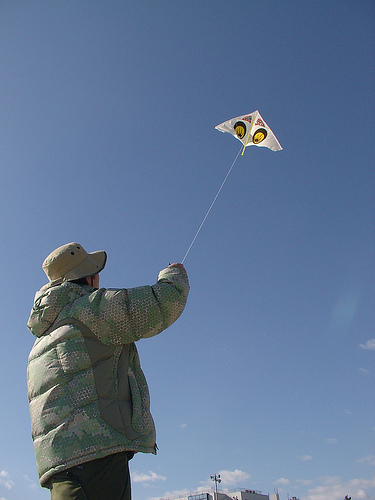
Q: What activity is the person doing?
A: Flying a kite.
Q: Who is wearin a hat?
A: The person.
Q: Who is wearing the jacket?
A: The person.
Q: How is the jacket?
A: Puffy.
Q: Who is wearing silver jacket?
A: The person.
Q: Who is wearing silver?
A: The person.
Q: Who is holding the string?
A: The person.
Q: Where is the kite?
A: Air.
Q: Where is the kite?
A: Sky.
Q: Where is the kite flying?
A: Sky.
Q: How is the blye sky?
A: Clear.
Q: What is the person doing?
A: Flying a kite.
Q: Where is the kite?
A: High in the sky.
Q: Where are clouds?
A: In the blue sky.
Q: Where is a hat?
A: On person's head.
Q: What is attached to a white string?
A: Kite.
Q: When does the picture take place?
A: During the daytime.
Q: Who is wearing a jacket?
A: The person.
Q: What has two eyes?
A: The kite.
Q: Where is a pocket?
A: On jacket.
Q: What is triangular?
A: A kite.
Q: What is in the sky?
A: Kite.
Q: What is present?
A: A person.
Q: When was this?
A: Daytime.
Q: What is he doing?
A: Playing.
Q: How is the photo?
A: Clear.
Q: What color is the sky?
A: Blue.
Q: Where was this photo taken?
A: In a park.